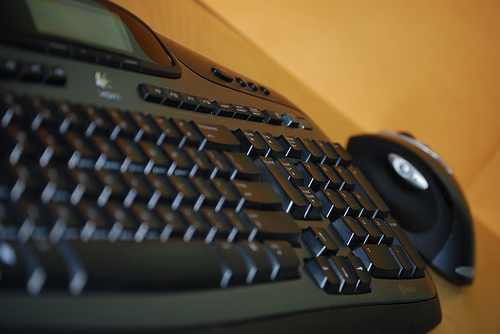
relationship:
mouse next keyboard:
[346, 131, 473, 286] [5, 3, 444, 325]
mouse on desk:
[345, 128, 479, 287] [112, 0, 497, 332]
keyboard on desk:
[3, 105, 330, 326] [444, 285, 499, 328]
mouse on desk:
[346, 131, 473, 286] [444, 285, 499, 328]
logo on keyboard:
[90, 63, 120, 103] [4, 52, 443, 326]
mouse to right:
[345, 128, 479, 287] [325, 104, 497, 277]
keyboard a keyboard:
[0, 0, 442, 332] [5, 3, 444, 325]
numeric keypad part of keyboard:
[308, 134, 418, 279] [2, 90, 417, 327]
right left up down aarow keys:
[161, 116, 370, 334] [298, 227, 370, 299]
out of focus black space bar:
[0, 54, 433, 306] [76, 227, 234, 299]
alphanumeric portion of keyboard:
[29, 79, 289, 334] [5, 3, 444, 325]